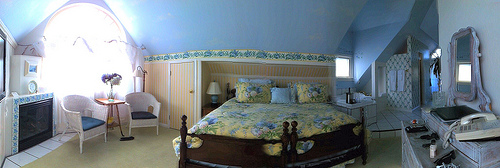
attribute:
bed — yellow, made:
[171, 79, 368, 167]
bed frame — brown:
[180, 83, 368, 167]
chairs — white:
[59, 91, 162, 154]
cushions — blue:
[80, 111, 157, 133]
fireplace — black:
[18, 98, 54, 154]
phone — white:
[443, 113, 499, 149]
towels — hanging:
[387, 70, 408, 95]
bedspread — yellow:
[173, 95, 371, 160]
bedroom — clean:
[0, 0, 498, 167]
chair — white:
[123, 91, 162, 138]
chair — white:
[59, 94, 110, 155]